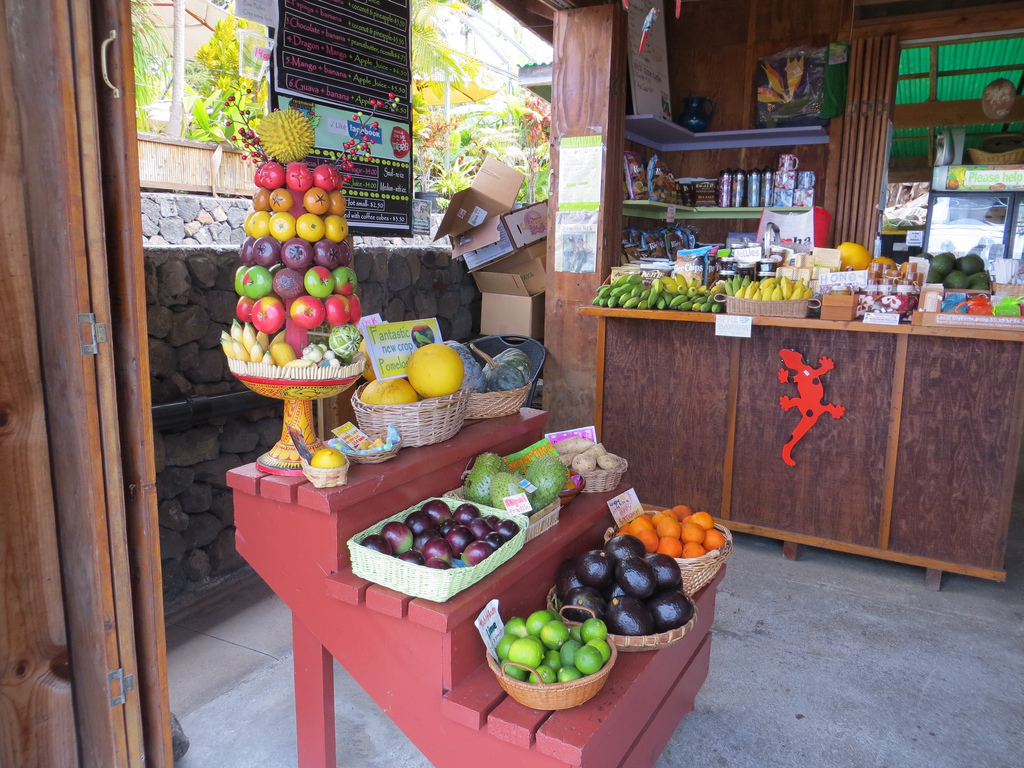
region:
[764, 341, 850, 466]
red and black salamander scultpure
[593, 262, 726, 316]
green bananas on counter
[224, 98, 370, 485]
fruit display on cake stand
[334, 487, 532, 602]
woven basket containing mangos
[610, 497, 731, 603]
woven basket containing oranges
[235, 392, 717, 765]
wood staircase painted light red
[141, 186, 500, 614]
rock wall inside store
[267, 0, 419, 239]
black board with flourescent words written on it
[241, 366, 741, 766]
Three tiered painted wooden stand.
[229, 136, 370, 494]
Tall decorative fruit tree bowl.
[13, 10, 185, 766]
Sliding wood door opening.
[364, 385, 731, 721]
Fruit and vegetables in baskets.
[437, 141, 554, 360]
Empty brown cardboard boxes.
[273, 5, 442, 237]
Product prices for customers.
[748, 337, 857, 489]
Red gecko/lizard stuck on counter.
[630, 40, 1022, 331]
Area crammed full of products.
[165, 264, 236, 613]
This wall made of rocks.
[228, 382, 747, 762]
fruits on top of stand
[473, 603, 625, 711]
lime inside a basket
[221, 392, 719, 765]
fruit stand is red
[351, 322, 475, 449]
grapefruit inside a basket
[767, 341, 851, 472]
lizard plaque on counter wall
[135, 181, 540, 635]
wall made of stones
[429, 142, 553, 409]
boxes next to stone wall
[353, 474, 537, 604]
a basket of fruit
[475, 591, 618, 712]
a bowl of fruit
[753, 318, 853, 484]
a red decorative lizard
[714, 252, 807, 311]
a group of bananas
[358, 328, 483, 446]
a basket of grapefruit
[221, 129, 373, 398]
a stack of fruits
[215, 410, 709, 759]
a display of fruit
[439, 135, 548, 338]
a pile of boxes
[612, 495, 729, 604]
basket of oranges on display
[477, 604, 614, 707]
basket of limes on display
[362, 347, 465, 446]
basket of grapefruit on display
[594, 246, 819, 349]
bananas on top of counter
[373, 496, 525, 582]
plums inside a basket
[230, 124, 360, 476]
fruit tree on display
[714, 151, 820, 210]
cups on top of shelf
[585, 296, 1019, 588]
counter is brown wood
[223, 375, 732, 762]
red display rack on floor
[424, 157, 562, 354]
boxes piled in corner